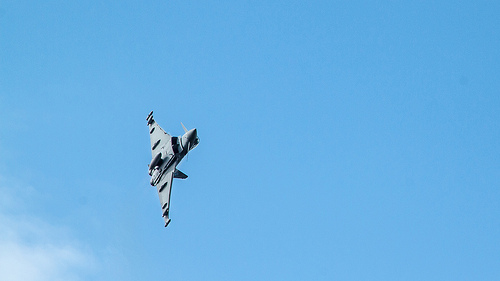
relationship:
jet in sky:
[143, 104, 198, 233] [4, 6, 495, 281]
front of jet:
[174, 122, 204, 156] [143, 104, 198, 233]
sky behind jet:
[4, 6, 495, 281] [143, 104, 198, 233]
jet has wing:
[143, 104, 198, 233] [142, 111, 167, 136]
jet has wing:
[143, 104, 198, 233] [160, 186, 179, 226]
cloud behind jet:
[8, 182, 64, 279] [143, 104, 198, 233]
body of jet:
[150, 145, 192, 176] [143, 104, 198, 233]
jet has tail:
[143, 104, 198, 233] [146, 160, 164, 181]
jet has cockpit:
[143, 104, 198, 233] [185, 138, 201, 149]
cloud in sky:
[8, 182, 64, 279] [4, 6, 495, 281]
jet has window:
[143, 104, 198, 233] [184, 139, 198, 150]